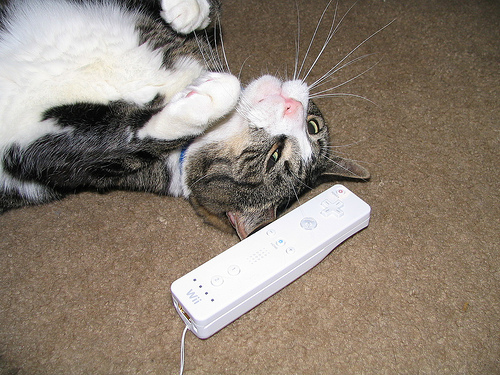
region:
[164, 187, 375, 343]
remote control for game console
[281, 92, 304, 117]
pink nose of a cat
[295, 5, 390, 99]
whiskers of a cat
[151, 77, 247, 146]
white paw of a cat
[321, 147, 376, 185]
ear on a cat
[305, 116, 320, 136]
brown and yellow eye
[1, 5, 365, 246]
black brown and white cat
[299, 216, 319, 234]
button on remote control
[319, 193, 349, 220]
directional arrow on remote control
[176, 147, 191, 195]
blue collar on cat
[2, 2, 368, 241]
the cat is upside down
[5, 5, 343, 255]
the cat is laying on the floor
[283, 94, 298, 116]
the cat has a pink nose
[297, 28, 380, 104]
the cat has wiskers growing out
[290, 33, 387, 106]
the wiskers are white in color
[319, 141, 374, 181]
the cat has pointy ears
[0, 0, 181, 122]
the cat has a white chest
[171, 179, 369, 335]
a remote controller is on the ground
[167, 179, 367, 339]
the remote is a video game controller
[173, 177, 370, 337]
the remote is white in color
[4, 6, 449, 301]
A cat laying on his back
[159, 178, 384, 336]
A game controller on floor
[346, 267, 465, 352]
Light brown carpet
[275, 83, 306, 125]
A cats pink nose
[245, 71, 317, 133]
A cats white mouth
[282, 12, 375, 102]
Cats white whiskers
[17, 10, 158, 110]
Cats white chest area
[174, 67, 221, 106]
Cats paw with pink pad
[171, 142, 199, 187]
A blue cat collar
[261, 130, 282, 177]
Cat's green and black eye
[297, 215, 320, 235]
a button on a controller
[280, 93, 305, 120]
the nose of the cat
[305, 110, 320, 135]
the eye of a cat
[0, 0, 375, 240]
a cat laying on the floor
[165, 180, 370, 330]
a white wiimote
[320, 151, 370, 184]
the ear of a cat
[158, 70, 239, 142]
the paw of a cat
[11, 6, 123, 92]
a white patch of cat fur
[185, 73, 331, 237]
the head of a cat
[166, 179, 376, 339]
a white controller on the floor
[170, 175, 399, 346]
White remote control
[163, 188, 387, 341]
White remote nitendo wii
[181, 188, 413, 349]
Beige carpet with white remote control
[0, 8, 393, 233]
Black striped cat laying on back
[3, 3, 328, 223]
Black striped cat with white fur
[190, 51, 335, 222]
Striped cat with green eyes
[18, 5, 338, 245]
Striped cat with paws up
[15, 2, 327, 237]
Cat looking at camera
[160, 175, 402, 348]
White remote control with buttons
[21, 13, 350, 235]
Striped cat have two ears